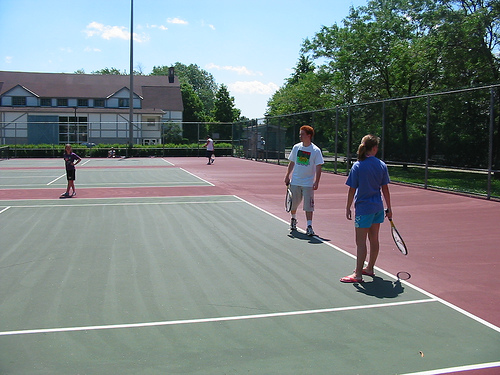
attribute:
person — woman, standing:
[334, 125, 404, 302]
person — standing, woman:
[341, 132, 391, 284]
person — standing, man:
[285, 125, 323, 238]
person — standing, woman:
[59, 143, 81, 198]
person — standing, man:
[201, 135, 213, 165]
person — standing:
[258, 135, 265, 162]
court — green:
[2, 151, 216, 194]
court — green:
[6, 192, 496, 373]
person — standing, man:
[201, 132, 218, 164]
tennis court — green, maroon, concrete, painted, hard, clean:
[0, 156, 499, 373]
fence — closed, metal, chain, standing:
[4, 119, 242, 160]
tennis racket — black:
[282, 181, 296, 215]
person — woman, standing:
[338, 132, 395, 286]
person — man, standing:
[281, 125, 326, 237]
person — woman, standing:
[57, 139, 84, 199]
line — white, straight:
[167, 162, 224, 191]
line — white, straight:
[385, 335, 498, 374]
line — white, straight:
[7, 191, 264, 213]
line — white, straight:
[214, 183, 496, 355]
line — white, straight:
[0, 287, 450, 347]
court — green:
[4, 163, 218, 200]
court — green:
[1, 148, 182, 170]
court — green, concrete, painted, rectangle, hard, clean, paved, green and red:
[5, 157, 490, 374]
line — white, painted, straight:
[1, 293, 443, 339]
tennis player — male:
[337, 124, 409, 296]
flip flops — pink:
[354, 260, 401, 288]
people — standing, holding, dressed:
[276, 122, 421, 293]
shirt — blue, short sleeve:
[351, 161, 389, 216]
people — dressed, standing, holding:
[278, 125, 402, 297]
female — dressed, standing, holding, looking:
[338, 130, 409, 286]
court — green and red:
[0, 140, 217, 200]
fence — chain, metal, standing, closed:
[229, 83, 488, 211]